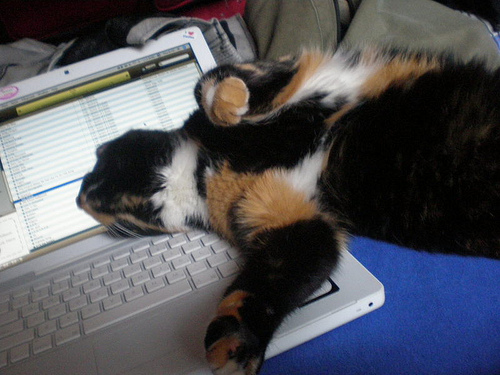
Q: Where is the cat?
A: Lying on a laptop.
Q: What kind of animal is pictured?
A: A cat.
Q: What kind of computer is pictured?
A: A laptop.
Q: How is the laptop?
A: Turned on.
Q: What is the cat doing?
A: Resting on the laptop.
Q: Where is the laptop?
A: On top of a blue fabric.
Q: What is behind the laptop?
A: A pile of clothes.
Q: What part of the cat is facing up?
A: The tummy.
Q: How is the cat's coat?
A: White, brown and black.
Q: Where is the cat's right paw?
A: On the computer.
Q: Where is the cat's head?
A: Computer.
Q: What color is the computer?
A: White.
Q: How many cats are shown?
A: One.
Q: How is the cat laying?
A: On back.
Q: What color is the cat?
A: Multicolor.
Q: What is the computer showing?
A: Email.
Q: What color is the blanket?
A: Blue.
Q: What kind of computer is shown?
A: Laptop.